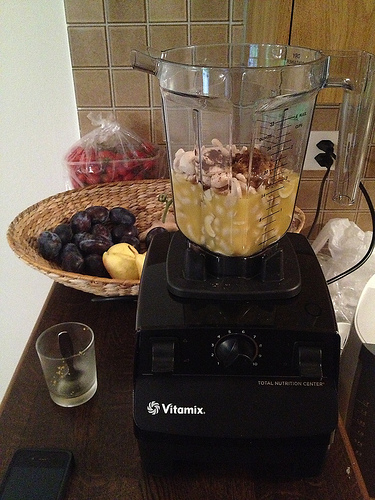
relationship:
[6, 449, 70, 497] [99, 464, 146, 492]
cellphone on top of table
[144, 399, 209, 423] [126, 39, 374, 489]
logo on front blender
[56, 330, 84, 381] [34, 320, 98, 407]
spoon in glass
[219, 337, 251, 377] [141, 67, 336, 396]
knob belongs on blender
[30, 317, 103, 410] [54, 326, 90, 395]
glass has spoon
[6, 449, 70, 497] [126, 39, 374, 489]
cellphone next to blender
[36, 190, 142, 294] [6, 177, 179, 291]
fruit in basket